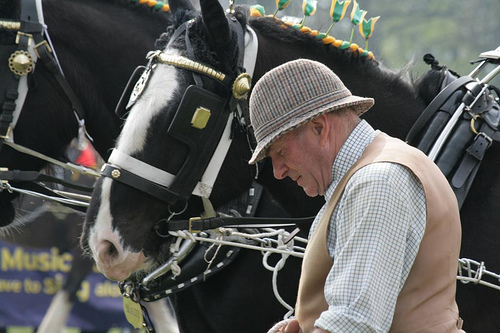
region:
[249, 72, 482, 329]
the man is old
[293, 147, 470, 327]
the half sweater is brown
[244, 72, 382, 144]
the hat is brown and blue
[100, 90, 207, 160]
white spot is on the head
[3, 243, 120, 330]
the banner is blue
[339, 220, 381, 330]
the shirt is checked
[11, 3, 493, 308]
the horses are two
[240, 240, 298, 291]
a knot is on the rope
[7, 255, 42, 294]
the letters are yellow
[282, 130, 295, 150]
wrinkles are on the eye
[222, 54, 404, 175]
man has grey cap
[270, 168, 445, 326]
man has brown vest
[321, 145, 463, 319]
man has blue and white shirt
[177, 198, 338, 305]
white rope near horse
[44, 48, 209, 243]
white stripe on horse's face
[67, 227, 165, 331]
horse has white nose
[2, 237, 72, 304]
blue and yellow sign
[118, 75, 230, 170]
black blinders on horse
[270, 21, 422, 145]
black fur on horse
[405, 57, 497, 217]
black belts on horse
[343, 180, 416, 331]
the shirt is white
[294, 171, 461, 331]
the half sweater is brown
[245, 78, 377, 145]
the hat is brown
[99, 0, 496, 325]
the horse is black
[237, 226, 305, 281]
the rope is white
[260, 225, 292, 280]
a knot is on the rope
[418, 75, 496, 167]
belt is on the sadle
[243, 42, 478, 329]
tha man is old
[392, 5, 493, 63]
the background is blurred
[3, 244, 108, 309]
music writen on the canvas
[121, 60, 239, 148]
blinders on the horse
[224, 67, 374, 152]
man is wearing a hat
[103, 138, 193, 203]
horse has strap across his nose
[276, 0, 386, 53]
horse's mane has green and yellow on the mane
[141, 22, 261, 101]
gold band near ear of horse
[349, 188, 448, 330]
man's shirt is checkered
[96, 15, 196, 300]
horse has white down the nose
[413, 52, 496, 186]
saddle of the horse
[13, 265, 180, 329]
white on the horse's feet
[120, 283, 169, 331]
yellow tag on the strap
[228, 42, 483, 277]
an older man walking next to the horse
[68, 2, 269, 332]
the horse has a harness on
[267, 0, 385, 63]
green and yellow design on horse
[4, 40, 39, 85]
a buckle on the horse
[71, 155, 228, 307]
the horses mouth up close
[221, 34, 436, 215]
the man is wearing a hat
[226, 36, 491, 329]
the man has a vest on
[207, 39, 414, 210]
the man is looking down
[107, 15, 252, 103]
there is something on the horses head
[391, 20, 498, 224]
the harness wraps around the horses back